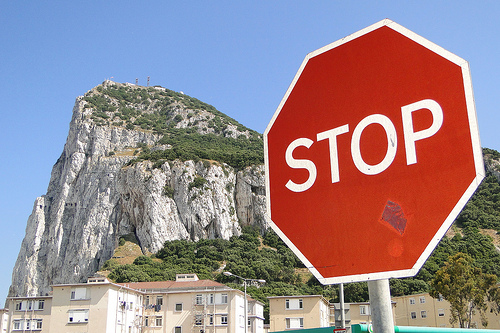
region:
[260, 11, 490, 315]
Red stop sign with white border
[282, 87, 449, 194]
white letters on red stop sign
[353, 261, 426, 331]
pole holding up red stop sign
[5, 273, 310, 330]
houses below large rock formation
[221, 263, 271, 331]
street lamp in front of houses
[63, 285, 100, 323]
windows on beige houses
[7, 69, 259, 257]
Large rock formation in background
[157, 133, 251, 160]
green trees on top of large rock formation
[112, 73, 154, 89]
towers on top of large rock formation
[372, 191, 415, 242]
Smudge on red stop sign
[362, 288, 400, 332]
the post is metallic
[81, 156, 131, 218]
the rocks are white in color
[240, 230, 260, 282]
the plants are green in color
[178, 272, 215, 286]
he roof tops are brown in color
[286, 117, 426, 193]
the words are written in white color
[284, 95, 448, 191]
words are written on red poster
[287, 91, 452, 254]
the poster is red in color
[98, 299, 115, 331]
the wall is light brown in color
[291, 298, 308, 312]
the windows are whiye in color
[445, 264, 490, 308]
the tree is green yellow in color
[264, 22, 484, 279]
stop sign is red and white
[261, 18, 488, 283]
stop sign is octagon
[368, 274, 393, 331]
metal pole holding up sign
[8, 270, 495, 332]
large tan building behind sign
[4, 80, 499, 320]
mountian is covered in trees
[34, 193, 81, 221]
buildings carved into moutainside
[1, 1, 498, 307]
sky is clear and blue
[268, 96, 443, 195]
the sign says "STOP"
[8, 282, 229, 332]
balconies outside building sides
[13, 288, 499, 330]
several windows on buildings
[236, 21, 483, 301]
red and whtie stop sign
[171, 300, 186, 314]
window on the side of the building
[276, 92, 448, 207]
white writing in all caps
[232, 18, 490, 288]
white border around the sign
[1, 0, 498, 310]
light blue sk with no clouds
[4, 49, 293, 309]
large gray cliff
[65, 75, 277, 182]
greenery growing out of the ground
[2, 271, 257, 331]
tan building with a brown roof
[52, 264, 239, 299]
roof of the building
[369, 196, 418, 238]
paint peeling off the sign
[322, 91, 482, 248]
this is a stop sign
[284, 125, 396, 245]
this is a sign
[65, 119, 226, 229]
this is a mountain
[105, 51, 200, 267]
this is a cliff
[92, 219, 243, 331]
this is a building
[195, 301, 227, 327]
this is a window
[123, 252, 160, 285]
this is a roof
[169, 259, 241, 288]
these are old trees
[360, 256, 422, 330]
this is a pole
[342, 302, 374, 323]
the pole is metal